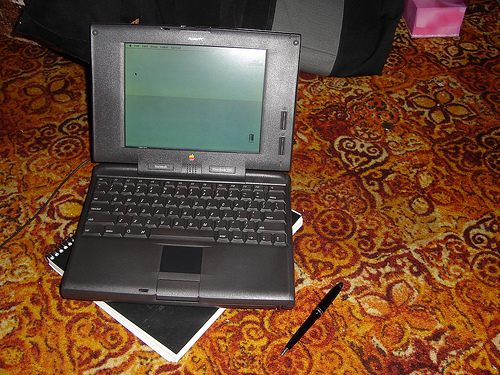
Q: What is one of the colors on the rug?
A: Orange.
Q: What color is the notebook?
A: Black.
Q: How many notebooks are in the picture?
A: One.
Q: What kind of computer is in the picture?
A: Laptop.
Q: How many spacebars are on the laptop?
A: One.